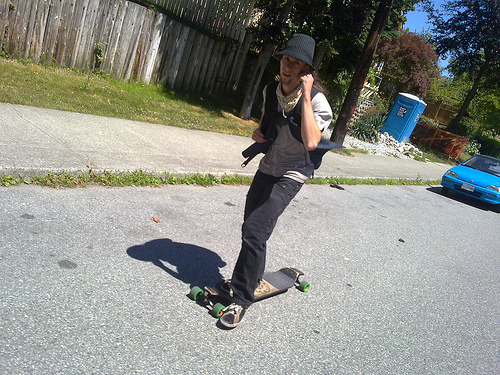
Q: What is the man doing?
A: Skating.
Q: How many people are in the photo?
A: One.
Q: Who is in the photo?
A: A man.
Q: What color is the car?
A: Blue.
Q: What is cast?
A: Shadow.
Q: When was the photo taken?
A: Daytime.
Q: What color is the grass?
A: Green.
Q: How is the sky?
A: Clear.